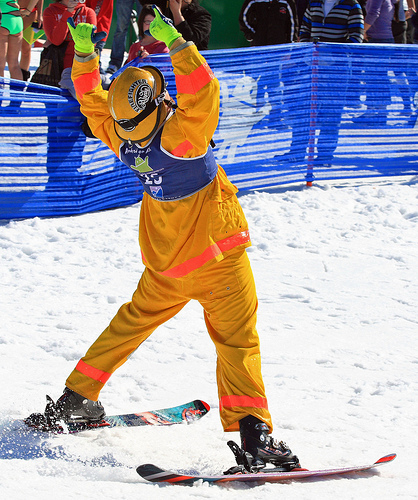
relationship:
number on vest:
[125, 151, 162, 191] [70, 39, 248, 277]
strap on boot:
[57, 389, 106, 420] [56, 390, 103, 424]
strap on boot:
[229, 416, 301, 469] [56, 390, 103, 424]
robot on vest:
[128, 150, 157, 174] [118, 123, 221, 200]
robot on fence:
[128, 150, 157, 174] [0, 38, 417, 217]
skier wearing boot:
[34, 13, 319, 465] [53, 371, 318, 471]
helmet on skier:
[102, 62, 184, 161] [24, 6, 399, 499]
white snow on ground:
[0, 100, 416, 497] [1, 117, 416, 498]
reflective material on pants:
[218, 392, 268, 408] [64, 250, 271, 430]